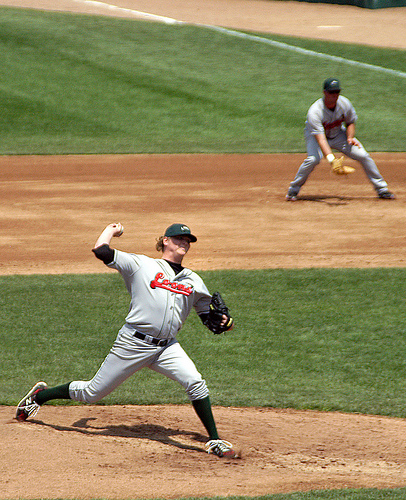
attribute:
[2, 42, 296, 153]
grass — green, brown, short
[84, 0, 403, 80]
lines — white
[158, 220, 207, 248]
hat — dark colored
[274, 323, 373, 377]
grass — patch, green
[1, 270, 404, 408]
grass — green, patch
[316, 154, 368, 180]
glove — brown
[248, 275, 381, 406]
grass — brown, short, green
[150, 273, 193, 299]
writing — red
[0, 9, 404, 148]
grass — green, short, brown